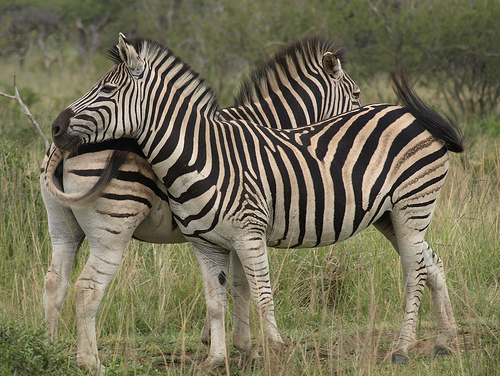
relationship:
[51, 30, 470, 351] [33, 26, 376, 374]
zebra by zebra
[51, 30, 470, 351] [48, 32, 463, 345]
zebra has black stripes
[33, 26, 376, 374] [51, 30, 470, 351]
zebra by zebra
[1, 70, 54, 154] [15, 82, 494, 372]
stick in field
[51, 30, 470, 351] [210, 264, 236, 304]
zebra has spot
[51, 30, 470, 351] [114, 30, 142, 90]
zebra has ear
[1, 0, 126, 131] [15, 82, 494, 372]
tree in field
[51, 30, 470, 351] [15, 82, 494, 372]
zebra in grass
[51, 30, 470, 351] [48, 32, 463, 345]
zebra has stripes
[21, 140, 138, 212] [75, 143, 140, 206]
tail has black portion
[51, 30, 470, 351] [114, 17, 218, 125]
zebra has mane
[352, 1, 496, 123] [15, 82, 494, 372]
tree in field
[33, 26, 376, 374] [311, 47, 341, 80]
zebra has ear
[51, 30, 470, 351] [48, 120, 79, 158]
zebra has nose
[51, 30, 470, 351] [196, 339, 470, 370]
zebra has hooves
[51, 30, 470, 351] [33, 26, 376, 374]
zebra next to zebra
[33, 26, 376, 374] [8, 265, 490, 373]
zebra standing on ground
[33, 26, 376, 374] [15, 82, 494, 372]
zebra in grass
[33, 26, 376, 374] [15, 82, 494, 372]
zebra in field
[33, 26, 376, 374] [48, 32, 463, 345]
zebra has black stripes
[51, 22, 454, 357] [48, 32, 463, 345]
fur has stripes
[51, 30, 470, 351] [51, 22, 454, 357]
zebra has white stripes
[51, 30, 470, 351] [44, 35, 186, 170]
zebra has head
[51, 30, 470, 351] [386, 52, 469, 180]
zebra has black tail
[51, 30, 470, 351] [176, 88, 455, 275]
zebra has body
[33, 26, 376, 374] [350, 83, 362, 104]
zebra has eye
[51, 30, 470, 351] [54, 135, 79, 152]
zebra has mouth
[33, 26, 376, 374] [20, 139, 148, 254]
zebra has rear end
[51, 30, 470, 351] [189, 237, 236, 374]
zebra has front leg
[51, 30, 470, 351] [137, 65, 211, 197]
zebra has neck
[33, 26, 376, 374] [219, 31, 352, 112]
zebra has mane